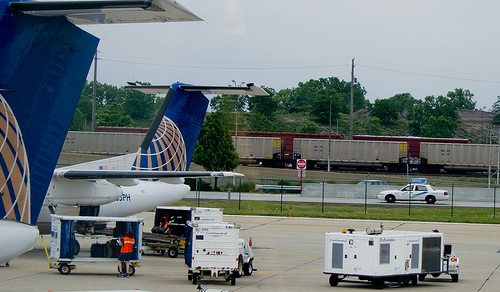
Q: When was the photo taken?
A: Daytime.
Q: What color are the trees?
A: Green.